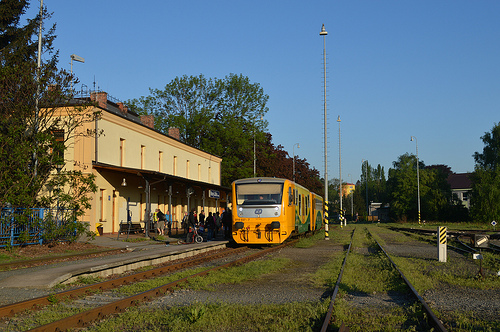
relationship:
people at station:
[149, 207, 233, 248] [23, 89, 237, 246]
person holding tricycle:
[182, 208, 199, 244] [186, 225, 205, 246]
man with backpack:
[154, 209, 169, 240] [159, 211, 167, 222]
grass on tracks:
[2, 231, 250, 331] [2, 193, 319, 329]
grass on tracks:
[319, 227, 445, 330] [307, 216, 451, 331]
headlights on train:
[237, 205, 243, 212] [228, 174, 330, 251]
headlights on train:
[273, 204, 279, 211] [228, 174, 330, 251]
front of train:
[230, 176, 288, 250] [228, 174, 330, 251]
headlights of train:
[237, 205, 243, 212] [228, 174, 330, 251]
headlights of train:
[273, 204, 279, 211] [228, 174, 330, 251]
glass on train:
[232, 176, 287, 214] [228, 174, 330, 251]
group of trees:
[131, 71, 346, 232] [131, 72, 332, 240]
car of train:
[227, 173, 311, 248] [228, 174, 330, 251]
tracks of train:
[2, 193, 319, 329] [228, 174, 330, 251]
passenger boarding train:
[217, 205, 234, 240] [228, 174, 330, 251]